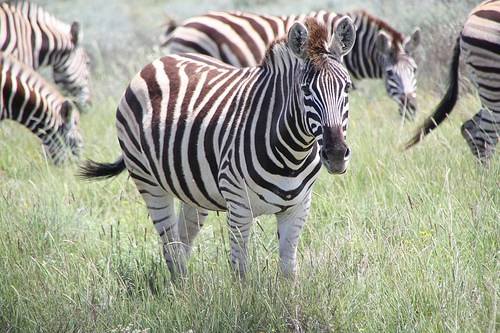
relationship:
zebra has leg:
[82, 22, 354, 311] [226, 202, 260, 302]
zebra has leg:
[82, 22, 354, 311] [275, 194, 307, 330]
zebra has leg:
[82, 22, 354, 311] [134, 180, 192, 295]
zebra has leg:
[82, 22, 354, 311] [176, 200, 206, 271]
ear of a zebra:
[286, 19, 312, 66] [79, 14, 352, 286]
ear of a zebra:
[329, 13, 358, 61] [91, 19, 360, 282]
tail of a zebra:
[74, 149, 126, 181] [82, 22, 354, 311]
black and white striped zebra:
[62, 106, 220, 278] [292, 151, 314, 202]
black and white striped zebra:
[22, 103, 34, 118] [3, 104, 85, 190]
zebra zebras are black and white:
[75, 16, 360, 298] [97, 117, 464, 237]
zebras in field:
[3, 7, 498, 175] [16, 237, 498, 331]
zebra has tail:
[404, 0, 493, 175] [393, 31, 462, 157]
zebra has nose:
[82, 22, 354, 311] [321, 147, 351, 170]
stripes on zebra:
[167, 64, 257, 154] [82, 22, 354, 311]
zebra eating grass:
[0, 52, 90, 184] [2, 136, 117, 218]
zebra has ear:
[160, 7, 425, 124] [407, 28, 421, 48]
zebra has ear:
[160, 7, 425, 124] [374, 29, 397, 58]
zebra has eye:
[82, 22, 354, 311] [299, 85, 315, 99]